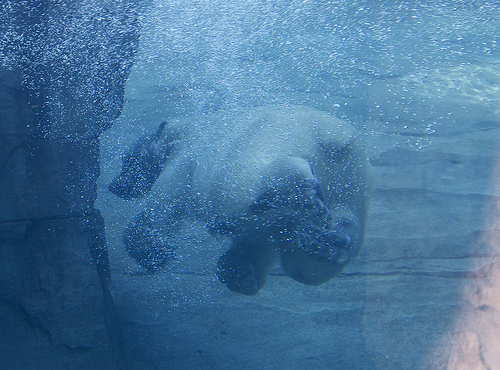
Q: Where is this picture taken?
A: Underwater.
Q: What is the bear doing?
A: Swimming.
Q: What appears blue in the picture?
A: Water.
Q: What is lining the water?
A: Rocks.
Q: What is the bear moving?
A: Legs.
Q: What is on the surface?
A: Bubbles.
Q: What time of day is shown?
A: Afternoon.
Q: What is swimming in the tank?
A: Polar bear.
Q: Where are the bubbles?
A: In the water.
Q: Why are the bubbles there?
A: Bears movement.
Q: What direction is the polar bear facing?
A: Away from camera.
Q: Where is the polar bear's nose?
A: On left.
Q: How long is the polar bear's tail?
A: It's a nub.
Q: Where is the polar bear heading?
A: Around rock.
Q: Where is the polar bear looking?
A: Behind rock.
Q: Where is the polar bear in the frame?
A: Middle.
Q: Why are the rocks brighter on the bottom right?
A: Sunlight.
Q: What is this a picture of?
A: A large polar bear, swimming underwater.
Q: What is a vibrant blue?
A: Most of the picture, because the scene is underwater.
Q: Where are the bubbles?
A: At the top of the picture, extending about a quarter of the way down, and behind the bear.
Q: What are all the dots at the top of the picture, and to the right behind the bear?
A: Bubbles.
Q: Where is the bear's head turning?
A: To the left.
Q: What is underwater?
A: Bear.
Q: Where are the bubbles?
A: In the water.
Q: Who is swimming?
A: The bear.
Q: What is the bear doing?
A: Swimming.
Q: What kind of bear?
A: Polar.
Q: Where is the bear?
A: Water.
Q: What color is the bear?
A: White.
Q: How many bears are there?
A: One.